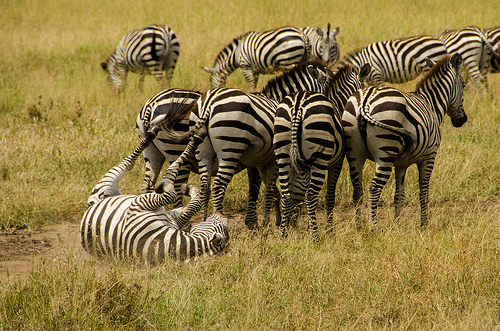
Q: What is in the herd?
A: Zebras.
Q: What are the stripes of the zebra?
A: Black and white.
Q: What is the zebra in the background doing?
A: Grazing.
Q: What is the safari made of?
A: Grass.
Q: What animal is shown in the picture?
A: Zebra.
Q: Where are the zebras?
A: Wild.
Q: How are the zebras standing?
A: Facing away from the camera.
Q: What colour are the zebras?
A: Black and white.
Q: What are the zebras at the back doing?
A: Eating grass.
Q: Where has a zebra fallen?
A: Ground.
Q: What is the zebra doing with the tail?
A: Wagging.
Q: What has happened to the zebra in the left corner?
A: Fallen.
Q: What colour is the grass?
A: Green.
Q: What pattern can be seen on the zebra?
A: Black and white stripes.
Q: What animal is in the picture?
A: Zebra.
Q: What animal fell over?
A: Zebra.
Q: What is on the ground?
A: Grass.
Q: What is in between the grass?
A: A dirt path.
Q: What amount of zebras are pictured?
A: 11.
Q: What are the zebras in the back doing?
A: Grazing.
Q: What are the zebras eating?
A: Grass.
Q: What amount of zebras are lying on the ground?
A: 1.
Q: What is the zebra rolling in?
A: Dirt.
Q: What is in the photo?
A: Zebras.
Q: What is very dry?
A: The grass.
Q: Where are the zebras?
A: In grass.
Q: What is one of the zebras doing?
A: Laying down.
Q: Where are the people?
A: No one in photo.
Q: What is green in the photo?
A: Grass.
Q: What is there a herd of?
A: Zebras.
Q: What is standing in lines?
A: Four zebras.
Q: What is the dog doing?
A: There is no dog.